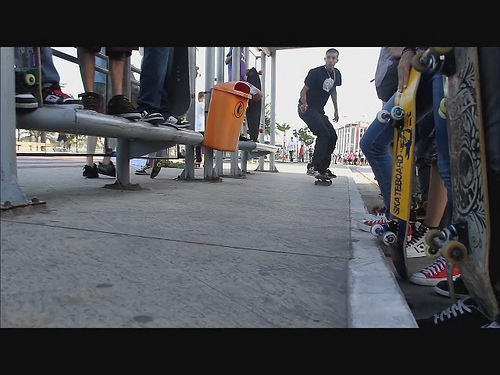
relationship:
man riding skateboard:
[298, 48, 344, 179] [314, 170, 335, 190]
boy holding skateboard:
[396, 40, 459, 258] [370, 64, 428, 288]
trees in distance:
[277, 120, 317, 168] [271, 45, 387, 163]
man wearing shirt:
[298, 48, 344, 179] [296, 66, 345, 112]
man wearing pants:
[298, 48, 344, 179] [293, 101, 339, 174]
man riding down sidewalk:
[298, 48, 344, 179] [5, 164, 349, 328]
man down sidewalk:
[298, 48, 344, 179] [5, 164, 349, 328]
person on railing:
[71, 42, 145, 120] [1, 46, 286, 209]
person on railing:
[137, 45, 187, 128] [1, 46, 286, 209]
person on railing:
[12, 41, 87, 117] [1, 46, 286, 209]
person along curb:
[365, 47, 447, 234] [347, 166, 420, 324]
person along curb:
[416, 47, 500, 331] [347, 166, 420, 324]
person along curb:
[407, 45, 474, 290] [347, 166, 420, 324]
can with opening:
[206, 79, 255, 155] [233, 79, 255, 96]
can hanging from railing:
[206, 79, 255, 155] [1, 46, 286, 209]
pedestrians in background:
[288, 141, 370, 164] [271, 45, 387, 163]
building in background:
[335, 114, 376, 165] [271, 45, 387, 163]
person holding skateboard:
[365, 47, 447, 234] [370, 64, 428, 288]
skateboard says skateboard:
[370, 64, 428, 288] [392, 151, 407, 217]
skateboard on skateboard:
[392, 151, 407, 217] [370, 64, 428, 288]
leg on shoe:
[112, 58, 129, 95] [105, 92, 144, 120]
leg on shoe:
[77, 51, 102, 93] [75, 91, 102, 117]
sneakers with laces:
[361, 213, 480, 322] [369, 211, 475, 319]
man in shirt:
[298, 48, 344, 179] [296, 66, 345, 112]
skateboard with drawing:
[410, 48, 500, 314] [449, 48, 478, 291]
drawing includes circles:
[449, 48, 478, 291] [457, 150, 475, 189]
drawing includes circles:
[449, 48, 478, 291] [451, 136, 481, 212]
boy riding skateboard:
[298, 48, 344, 179] [314, 170, 335, 190]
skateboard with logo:
[370, 64, 428, 288] [393, 112, 413, 217]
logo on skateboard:
[393, 112, 413, 217] [370, 64, 428, 288]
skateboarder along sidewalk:
[416, 47, 500, 331] [5, 164, 349, 328]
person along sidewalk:
[359, 45, 462, 284] [5, 164, 349, 328]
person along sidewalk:
[416, 47, 500, 331] [5, 164, 349, 328]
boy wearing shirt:
[298, 48, 344, 179] [296, 66, 345, 112]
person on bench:
[71, 42, 145, 120] [3, 46, 286, 209]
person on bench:
[137, 45, 187, 128] [3, 46, 286, 209]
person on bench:
[12, 41, 87, 117] [3, 46, 286, 209]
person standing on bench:
[137, 45, 187, 128] [3, 46, 286, 209]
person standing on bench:
[71, 42, 145, 120] [3, 46, 286, 209]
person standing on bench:
[12, 41, 87, 117] [3, 46, 286, 209]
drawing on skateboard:
[449, 48, 478, 291] [410, 48, 500, 314]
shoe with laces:
[105, 92, 144, 120] [110, 94, 134, 110]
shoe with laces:
[75, 91, 102, 117] [75, 91, 101, 104]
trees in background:
[277, 120, 317, 168] [271, 45, 387, 163]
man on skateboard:
[298, 48, 344, 179] [314, 170, 335, 190]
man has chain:
[298, 48, 344, 179] [324, 66, 340, 82]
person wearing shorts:
[71, 42, 145, 120] [73, 48, 134, 61]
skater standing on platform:
[12, 41, 87, 117] [1, 46, 286, 209]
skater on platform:
[12, 41, 87, 117] [1, 46, 286, 209]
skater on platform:
[137, 45, 187, 128] [1, 46, 286, 209]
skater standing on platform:
[137, 45, 187, 128] [1, 46, 286, 209]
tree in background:
[276, 121, 290, 162] [271, 45, 387, 163]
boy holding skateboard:
[416, 47, 500, 331] [410, 48, 500, 314]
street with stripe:
[351, 161, 385, 211] [353, 164, 382, 202]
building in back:
[335, 114, 376, 165] [271, 45, 387, 163]